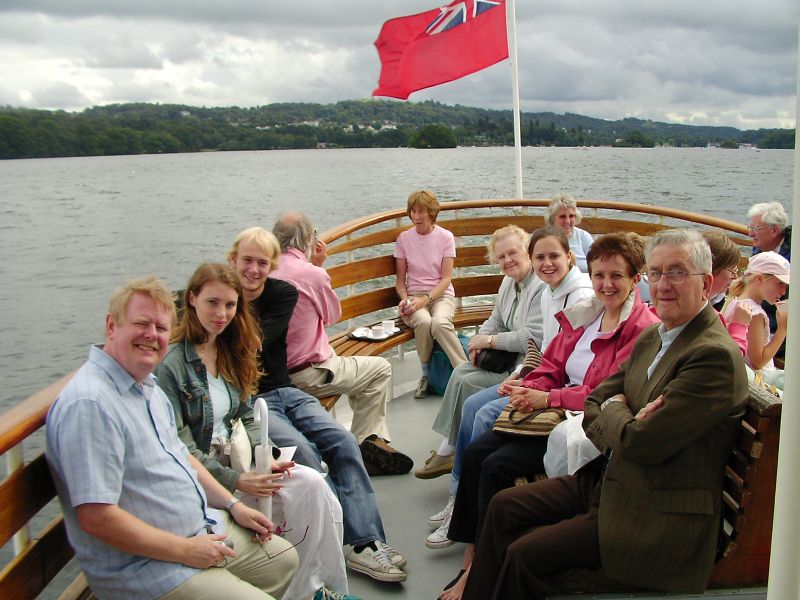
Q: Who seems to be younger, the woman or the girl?
A: The girl is younger than the woman.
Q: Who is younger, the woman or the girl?
A: The girl is younger than the woman.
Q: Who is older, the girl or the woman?
A: The woman is older than the girl.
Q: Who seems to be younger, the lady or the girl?
A: The girl is younger than the lady.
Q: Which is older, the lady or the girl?
A: The lady is older than the girl.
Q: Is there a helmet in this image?
A: No, there are no helmets.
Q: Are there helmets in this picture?
A: No, there are no helmets.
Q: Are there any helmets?
A: No, there are no helmets.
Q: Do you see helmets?
A: No, there are no helmets.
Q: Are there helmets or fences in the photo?
A: No, there are no helmets or fences.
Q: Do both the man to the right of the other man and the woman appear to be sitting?
A: Yes, both the man and the woman are sitting.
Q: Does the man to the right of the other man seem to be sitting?
A: Yes, the man is sitting.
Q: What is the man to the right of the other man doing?
A: The man is sitting.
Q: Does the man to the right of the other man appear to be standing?
A: No, the man is sitting.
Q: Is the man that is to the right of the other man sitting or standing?
A: The man is sitting.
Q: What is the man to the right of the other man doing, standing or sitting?
A: The man is sitting.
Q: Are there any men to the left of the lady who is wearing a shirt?
A: Yes, there is a man to the left of the lady.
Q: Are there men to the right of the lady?
A: No, the man is to the left of the lady.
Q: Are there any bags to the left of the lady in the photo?
A: No, there is a man to the left of the lady.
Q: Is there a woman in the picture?
A: Yes, there is a woman.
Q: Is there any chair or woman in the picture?
A: Yes, there is a woman.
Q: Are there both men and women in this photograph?
A: Yes, there are both a woman and a man.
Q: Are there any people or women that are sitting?
A: Yes, the woman is sitting.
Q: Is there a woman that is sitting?
A: Yes, there is a woman that is sitting.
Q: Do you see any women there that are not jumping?
A: Yes, there is a woman that is sitting .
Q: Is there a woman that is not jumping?
A: Yes, there is a woman that is sitting.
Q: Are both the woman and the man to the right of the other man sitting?
A: Yes, both the woman and the man are sitting.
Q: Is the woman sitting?
A: Yes, the woman is sitting.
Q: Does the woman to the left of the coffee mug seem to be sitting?
A: Yes, the woman is sitting.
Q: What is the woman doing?
A: The woman is sitting.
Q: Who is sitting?
A: The woman is sitting.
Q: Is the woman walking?
A: No, the woman is sitting.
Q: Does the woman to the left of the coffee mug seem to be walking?
A: No, the woman is sitting.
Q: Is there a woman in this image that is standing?
A: No, there is a woman but she is sitting.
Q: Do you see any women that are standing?
A: No, there is a woman but she is sitting.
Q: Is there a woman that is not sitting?
A: No, there is a woman but she is sitting.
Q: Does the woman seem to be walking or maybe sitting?
A: The woman is sitting.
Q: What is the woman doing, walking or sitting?
A: The woman is sitting.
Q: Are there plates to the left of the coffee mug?
A: No, there is a woman to the left of the coffee mug.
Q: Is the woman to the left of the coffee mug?
A: Yes, the woman is to the left of the coffee mug.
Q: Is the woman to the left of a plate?
A: No, the woman is to the left of the coffee mug.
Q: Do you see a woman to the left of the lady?
A: Yes, there is a woman to the left of the lady.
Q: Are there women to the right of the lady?
A: No, the woman is to the left of the lady.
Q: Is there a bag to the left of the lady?
A: No, there is a woman to the left of the lady.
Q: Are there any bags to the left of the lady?
A: No, there is a woman to the left of the lady.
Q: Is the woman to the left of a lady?
A: Yes, the woman is to the left of a lady.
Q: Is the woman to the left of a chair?
A: No, the woman is to the left of a lady.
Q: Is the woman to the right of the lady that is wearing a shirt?
A: No, the woman is to the left of the lady.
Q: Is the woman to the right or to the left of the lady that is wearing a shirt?
A: The woman is to the left of the lady.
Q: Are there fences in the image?
A: No, there are no fences.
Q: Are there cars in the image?
A: No, there are no cars.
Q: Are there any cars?
A: No, there are no cars.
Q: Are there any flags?
A: Yes, there is a flag.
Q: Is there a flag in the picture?
A: Yes, there is a flag.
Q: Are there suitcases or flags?
A: Yes, there is a flag.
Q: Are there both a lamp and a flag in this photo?
A: No, there is a flag but no lamps.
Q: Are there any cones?
A: No, there are no cones.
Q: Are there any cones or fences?
A: No, there are no cones or fences.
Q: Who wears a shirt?
A: The man wears a shirt.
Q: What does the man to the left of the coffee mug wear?
A: The man wears a shirt.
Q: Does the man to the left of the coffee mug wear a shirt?
A: Yes, the man wears a shirt.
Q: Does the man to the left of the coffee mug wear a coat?
A: No, the man wears a shirt.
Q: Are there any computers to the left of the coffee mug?
A: No, there is a man to the left of the coffee mug.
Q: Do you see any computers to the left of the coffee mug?
A: No, there is a man to the left of the coffee mug.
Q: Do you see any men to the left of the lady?
A: Yes, there is a man to the left of the lady.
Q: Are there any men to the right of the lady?
A: No, the man is to the left of the lady.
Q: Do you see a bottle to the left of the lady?
A: No, there is a man to the left of the lady.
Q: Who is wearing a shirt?
A: The lady is wearing a shirt.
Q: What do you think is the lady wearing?
A: The lady is wearing a shirt.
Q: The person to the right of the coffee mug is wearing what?
A: The lady is wearing a shirt.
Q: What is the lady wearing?
A: The lady is wearing a shirt.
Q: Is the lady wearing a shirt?
A: Yes, the lady is wearing a shirt.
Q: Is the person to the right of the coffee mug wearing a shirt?
A: Yes, the lady is wearing a shirt.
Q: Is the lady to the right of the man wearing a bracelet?
A: No, the lady is wearing a shirt.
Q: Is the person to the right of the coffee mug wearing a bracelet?
A: No, the lady is wearing a shirt.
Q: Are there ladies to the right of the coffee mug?
A: Yes, there is a lady to the right of the coffee mug.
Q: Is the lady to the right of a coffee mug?
A: Yes, the lady is to the right of a coffee mug.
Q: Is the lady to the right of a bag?
A: No, the lady is to the right of a coffee mug.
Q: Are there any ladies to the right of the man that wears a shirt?
A: Yes, there is a lady to the right of the man.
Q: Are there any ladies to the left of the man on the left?
A: No, the lady is to the right of the man.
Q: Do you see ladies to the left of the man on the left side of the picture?
A: No, the lady is to the right of the man.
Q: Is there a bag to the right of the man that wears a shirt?
A: No, there is a lady to the right of the man.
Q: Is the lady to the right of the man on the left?
A: Yes, the lady is to the right of the man.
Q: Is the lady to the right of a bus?
A: No, the lady is to the right of the man.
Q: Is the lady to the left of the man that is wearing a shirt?
A: No, the lady is to the right of the man.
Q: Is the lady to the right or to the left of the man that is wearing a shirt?
A: The lady is to the right of the man.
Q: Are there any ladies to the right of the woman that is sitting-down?
A: Yes, there is a lady to the right of the woman.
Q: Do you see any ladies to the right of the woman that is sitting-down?
A: Yes, there is a lady to the right of the woman.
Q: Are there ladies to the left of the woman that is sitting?
A: No, the lady is to the right of the woman.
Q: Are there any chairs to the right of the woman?
A: No, there is a lady to the right of the woman.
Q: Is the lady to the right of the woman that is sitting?
A: Yes, the lady is to the right of the woman.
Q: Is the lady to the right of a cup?
A: No, the lady is to the right of the woman.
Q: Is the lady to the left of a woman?
A: No, the lady is to the right of a woman.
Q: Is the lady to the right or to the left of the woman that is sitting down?
A: The lady is to the right of the woman.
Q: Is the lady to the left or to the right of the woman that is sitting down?
A: The lady is to the right of the woman.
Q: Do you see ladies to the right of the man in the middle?
A: Yes, there is a lady to the right of the man.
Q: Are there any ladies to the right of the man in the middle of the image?
A: Yes, there is a lady to the right of the man.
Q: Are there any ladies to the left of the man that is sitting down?
A: No, the lady is to the right of the man.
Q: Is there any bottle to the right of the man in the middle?
A: No, there is a lady to the right of the man.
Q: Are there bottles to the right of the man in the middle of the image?
A: No, there is a lady to the right of the man.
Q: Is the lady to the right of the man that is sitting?
A: Yes, the lady is to the right of the man.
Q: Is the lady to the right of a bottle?
A: No, the lady is to the right of the man.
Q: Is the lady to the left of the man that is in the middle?
A: No, the lady is to the right of the man.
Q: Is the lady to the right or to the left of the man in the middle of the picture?
A: The lady is to the right of the man.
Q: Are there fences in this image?
A: No, there are no fences.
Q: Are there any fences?
A: No, there are no fences.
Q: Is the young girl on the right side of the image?
A: Yes, the girl is on the right of the image.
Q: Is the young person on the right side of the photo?
A: Yes, the girl is on the right of the image.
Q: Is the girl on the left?
A: No, the girl is on the right of the image.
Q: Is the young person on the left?
A: No, the girl is on the right of the image.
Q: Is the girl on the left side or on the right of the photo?
A: The girl is on the right of the image.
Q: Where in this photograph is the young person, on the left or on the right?
A: The girl is on the right of the image.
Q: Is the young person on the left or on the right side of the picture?
A: The girl is on the right of the image.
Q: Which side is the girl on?
A: The girl is on the right of the image.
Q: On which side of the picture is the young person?
A: The girl is on the right of the image.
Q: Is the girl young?
A: Yes, the girl is young.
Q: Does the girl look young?
A: Yes, the girl is young.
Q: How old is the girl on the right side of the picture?
A: The girl is young.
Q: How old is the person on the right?
A: The girl is young.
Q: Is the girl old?
A: No, the girl is young.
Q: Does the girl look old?
A: No, the girl is young.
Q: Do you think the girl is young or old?
A: The girl is young.